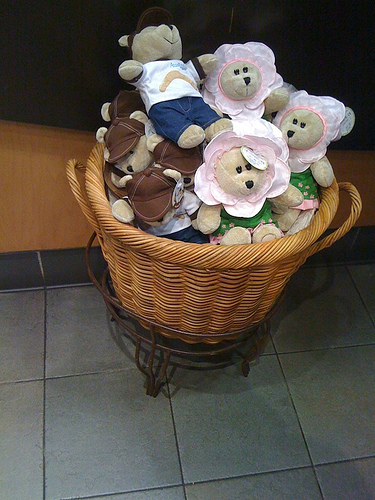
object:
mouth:
[237, 190, 259, 196]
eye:
[234, 165, 242, 175]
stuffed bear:
[202, 39, 288, 118]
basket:
[60, 137, 364, 348]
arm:
[196, 201, 222, 236]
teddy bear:
[192, 129, 305, 246]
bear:
[268, 85, 356, 234]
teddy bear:
[111, 163, 187, 229]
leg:
[111, 191, 137, 224]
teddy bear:
[95, 111, 157, 174]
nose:
[124, 164, 134, 174]